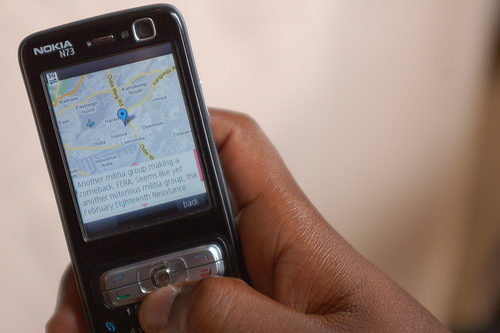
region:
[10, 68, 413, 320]
a person holding a phone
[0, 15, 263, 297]
the phone is black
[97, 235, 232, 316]
the keys are silver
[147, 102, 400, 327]
the hand is brown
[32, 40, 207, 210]
map quest is on the screen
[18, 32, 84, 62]
the phone is made by nokia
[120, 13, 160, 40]
the camera on the phone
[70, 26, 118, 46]
the speaker to hear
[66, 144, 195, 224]
words describing a location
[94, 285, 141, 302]
a green button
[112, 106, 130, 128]
a small blue dot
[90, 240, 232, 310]
a few silver buttons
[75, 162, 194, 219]
some writing on a phone screen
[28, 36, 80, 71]
the brand of a phone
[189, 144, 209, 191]
a thin red line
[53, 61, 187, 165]
a map on a screen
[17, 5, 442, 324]
a hand holding a phone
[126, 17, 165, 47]
the lens of a camera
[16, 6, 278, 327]
a small black phone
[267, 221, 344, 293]
some wrinkles on a hand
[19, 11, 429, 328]
Cellphone in person's hand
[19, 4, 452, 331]
Black cellphone in person's hand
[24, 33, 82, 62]
Nokia on black cellphone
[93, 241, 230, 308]
Silver button black phone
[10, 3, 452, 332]
Black phone in person's hand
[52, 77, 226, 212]
Street map on cellphone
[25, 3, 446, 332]
Black cellphone with street map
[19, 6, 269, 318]
Black cellphone with silver button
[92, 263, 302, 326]
finger pressing cell button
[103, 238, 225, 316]
Silver function button on cellphone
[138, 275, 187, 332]
nail on the thumb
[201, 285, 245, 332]
wrinkles on the thumb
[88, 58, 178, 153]
map on the phone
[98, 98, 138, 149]
point on the map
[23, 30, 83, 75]
maker of the phone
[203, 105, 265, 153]
knuckle on the finger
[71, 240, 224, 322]
buttons on the phone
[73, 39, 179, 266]
face of the phone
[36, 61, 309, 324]
cell phone in a hand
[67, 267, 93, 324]
finger bvehind the cell phone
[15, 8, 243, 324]
black Nokia cell phone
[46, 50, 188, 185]
map on a cell phone screen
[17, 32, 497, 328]
hand holding a cell phone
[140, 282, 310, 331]
thumb of the hand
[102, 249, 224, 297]
cellphone buttons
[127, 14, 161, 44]
camera on the black cell phone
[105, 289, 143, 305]
button labled green on cell phone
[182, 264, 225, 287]
button labeled red on cellphone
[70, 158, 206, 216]
text under the map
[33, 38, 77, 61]
Cellphone make and model